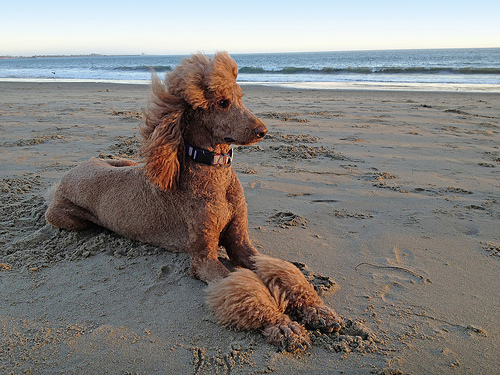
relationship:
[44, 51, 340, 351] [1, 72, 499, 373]
poodle on beach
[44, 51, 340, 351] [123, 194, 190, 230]
poodle that brown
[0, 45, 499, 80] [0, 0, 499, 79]
ocean in background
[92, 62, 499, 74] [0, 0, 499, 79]
waves in background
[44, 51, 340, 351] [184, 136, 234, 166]
poodle that has a collar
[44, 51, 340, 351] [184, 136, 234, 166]
poodle has a collar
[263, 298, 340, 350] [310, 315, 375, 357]
dog's paws are covered in sand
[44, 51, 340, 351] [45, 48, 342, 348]
poodle has a poodle haircut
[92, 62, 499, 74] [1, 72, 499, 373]
waves hitting beach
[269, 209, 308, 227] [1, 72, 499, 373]
foot prints on beach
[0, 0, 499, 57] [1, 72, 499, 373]
clear sky above beach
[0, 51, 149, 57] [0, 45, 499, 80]
land across water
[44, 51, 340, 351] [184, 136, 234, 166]
poodle with a collar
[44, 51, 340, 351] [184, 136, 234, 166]
poodle wearing a collar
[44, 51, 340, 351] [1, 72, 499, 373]
poodle laying on beach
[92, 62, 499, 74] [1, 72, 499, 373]
waves on beach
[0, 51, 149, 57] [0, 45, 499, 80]
land across ocean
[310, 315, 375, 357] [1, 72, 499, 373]
sand on beach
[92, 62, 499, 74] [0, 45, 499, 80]
waves in ocean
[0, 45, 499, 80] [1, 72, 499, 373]
ocean meets beach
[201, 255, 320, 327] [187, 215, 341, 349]
tufts of hair on poodle's legs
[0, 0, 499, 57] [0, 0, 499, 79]
clear sky in background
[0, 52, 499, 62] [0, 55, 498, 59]
line of horizon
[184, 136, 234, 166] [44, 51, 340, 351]
collar on poodle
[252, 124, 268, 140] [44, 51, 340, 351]
nose of poodle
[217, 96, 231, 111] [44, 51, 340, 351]
eye of poodle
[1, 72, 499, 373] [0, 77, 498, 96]
beach that wet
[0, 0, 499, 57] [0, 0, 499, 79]
clear sky that cloudless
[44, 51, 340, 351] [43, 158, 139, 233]
poodle that sitting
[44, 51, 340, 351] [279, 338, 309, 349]
poodle has claws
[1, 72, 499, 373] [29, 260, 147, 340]
beach that brown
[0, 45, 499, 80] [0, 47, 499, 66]
ocean that calm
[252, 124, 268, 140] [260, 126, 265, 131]
nose that black